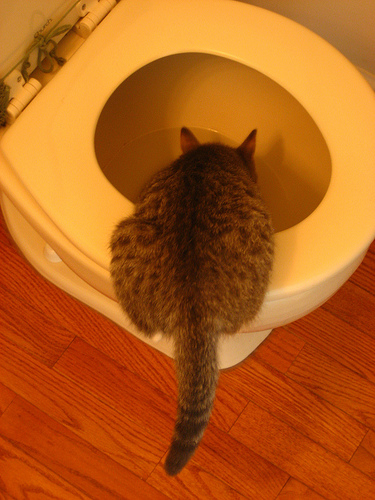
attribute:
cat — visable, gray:
[108, 124, 264, 476]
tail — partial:
[162, 321, 215, 474]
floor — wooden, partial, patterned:
[1, 204, 374, 499]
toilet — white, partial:
[3, 3, 374, 375]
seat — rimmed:
[3, 4, 374, 312]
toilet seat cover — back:
[1, 1, 78, 80]